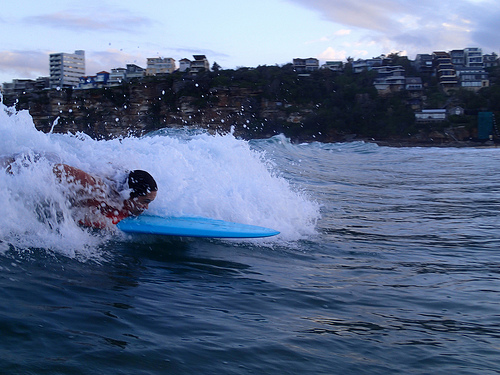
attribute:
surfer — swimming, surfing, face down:
[1, 156, 161, 217]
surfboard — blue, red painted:
[130, 212, 284, 247]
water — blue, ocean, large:
[258, 128, 489, 374]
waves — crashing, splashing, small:
[107, 131, 305, 235]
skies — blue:
[3, 3, 484, 57]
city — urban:
[17, 56, 479, 142]